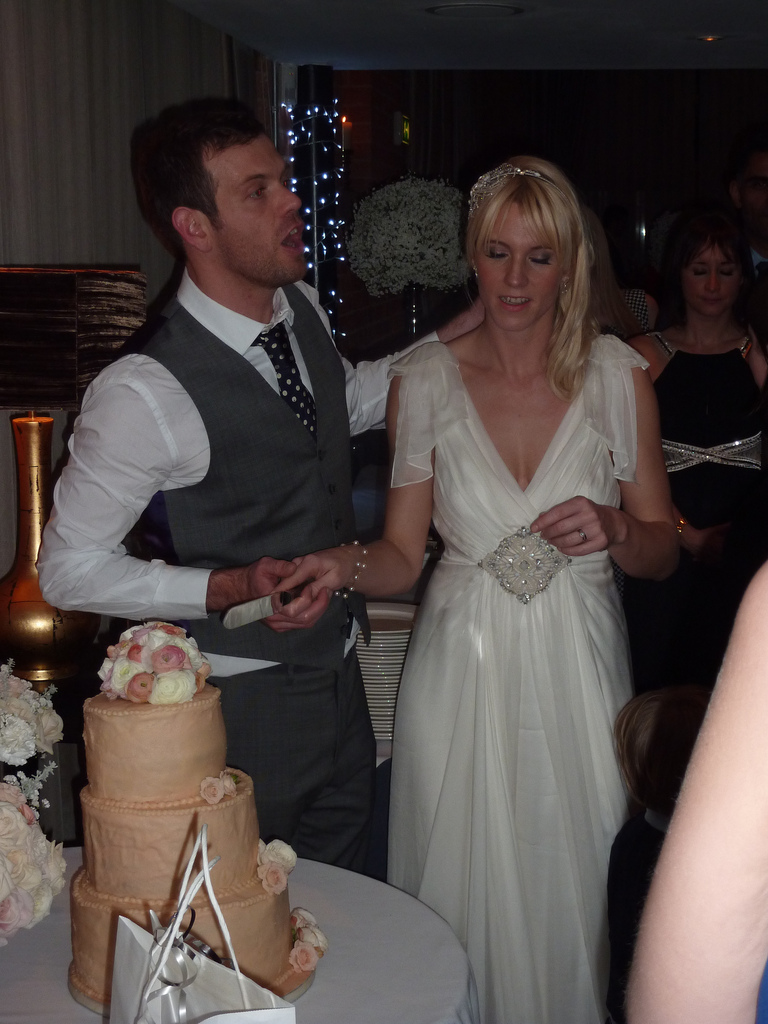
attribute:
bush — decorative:
[344, 179, 476, 296]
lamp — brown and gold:
[0, 267, 149, 680]